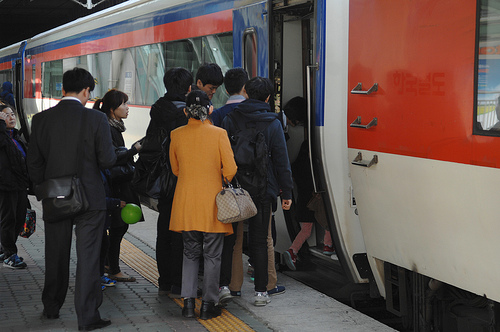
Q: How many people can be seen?
A: 8.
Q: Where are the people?
A: At a train station.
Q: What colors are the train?
A: Red, white and blue.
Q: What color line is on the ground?
A: Yellow.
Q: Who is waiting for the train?
A: Men and women.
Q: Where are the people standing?
A: On a platform.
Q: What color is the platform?
A: Gray.